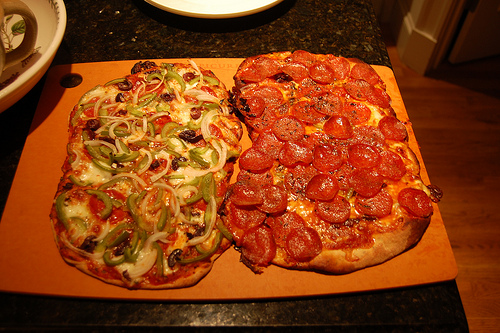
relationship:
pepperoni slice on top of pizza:
[284, 225, 322, 263] [213, 50, 444, 275]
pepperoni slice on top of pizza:
[399, 187, 434, 218] [213, 50, 444, 275]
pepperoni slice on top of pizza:
[306, 173, 341, 201] [213, 50, 444, 275]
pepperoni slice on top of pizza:
[323, 114, 355, 140] [213, 50, 444, 275]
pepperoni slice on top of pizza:
[378, 115, 408, 143] [213, 50, 444, 275]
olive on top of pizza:
[86, 118, 99, 130] [47, 59, 244, 290]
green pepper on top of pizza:
[165, 71, 187, 95] [47, 59, 244, 290]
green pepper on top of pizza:
[85, 184, 115, 218] [47, 59, 244, 290]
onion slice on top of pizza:
[200, 108, 221, 142] [47, 59, 244, 290]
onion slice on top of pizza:
[153, 175, 181, 223] [47, 59, 244, 290]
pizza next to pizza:
[213, 50, 444, 275] [47, 59, 244, 290]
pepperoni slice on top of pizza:
[309, 62, 335, 85] [213, 50, 444, 275]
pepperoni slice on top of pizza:
[350, 61, 380, 86] [213, 50, 444, 275]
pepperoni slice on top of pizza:
[236, 95, 266, 118] [213, 50, 444, 275]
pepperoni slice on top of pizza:
[239, 224, 275, 266] [213, 50, 444, 275]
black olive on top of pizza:
[131, 61, 144, 74] [47, 59, 244, 290]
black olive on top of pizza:
[168, 250, 183, 267] [47, 59, 244, 290]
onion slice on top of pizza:
[109, 174, 147, 188] [47, 59, 244, 290]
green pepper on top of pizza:
[55, 187, 72, 231] [47, 59, 244, 290]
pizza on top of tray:
[213, 50, 444, 275] [0, 56, 459, 302]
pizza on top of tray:
[47, 59, 244, 290] [0, 56, 459, 302]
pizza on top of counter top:
[213, 50, 444, 275] [0, 0, 468, 332]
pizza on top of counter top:
[47, 59, 244, 290] [0, 0, 468, 332]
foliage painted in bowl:
[12, 19, 26, 37] [0, 0, 67, 114]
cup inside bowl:
[1, 1, 39, 71] [0, 0, 67, 114]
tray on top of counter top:
[0, 56, 459, 302] [0, 0, 468, 332]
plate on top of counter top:
[143, 0, 285, 19] [0, 0, 468, 332]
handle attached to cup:
[4, 2, 39, 68] [1, 1, 39, 71]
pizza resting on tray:
[213, 50, 444, 275] [0, 56, 459, 302]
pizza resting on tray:
[47, 59, 244, 290] [0, 56, 459, 302]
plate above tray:
[143, 0, 285, 19] [0, 56, 459, 302]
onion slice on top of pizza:
[109, 120, 122, 140] [47, 59, 244, 290]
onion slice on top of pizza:
[188, 56, 204, 88] [47, 59, 244, 290]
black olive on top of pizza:
[86, 118, 99, 130] [47, 59, 244, 290]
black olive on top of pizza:
[80, 234, 97, 252] [47, 59, 244, 290]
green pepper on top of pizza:
[202, 171, 213, 203] [47, 59, 244, 290]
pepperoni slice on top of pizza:
[257, 186, 289, 214] [213, 50, 444, 275]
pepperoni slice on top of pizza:
[271, 115, 306, 143] [213, 50, 444, 275]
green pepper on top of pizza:
[125, 194, 151, 234] [47, 59, 244, 290]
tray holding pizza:
[0, 56, 459, 302] [213, 50, 444, 275]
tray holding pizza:
[0, 56, 459, 302] [47, 59, 244, 290]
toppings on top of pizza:
[58, 57, 236, 279] [47, 59, 244, 290]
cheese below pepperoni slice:
[362, 100, 382, 128] [343, 102, 371, 124]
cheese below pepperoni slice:
[271, 139, 430, 249] [399, 187, 434, 218]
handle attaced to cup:
[4, 2, 39, 68] [1, 1, 39, 71]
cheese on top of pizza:
[271, 139, 430, 249] [213, 50, 444, 275]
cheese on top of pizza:
[66, 201, 125, 269] [47, 59, 244, 290]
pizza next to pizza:
[47, 59, 244, 290] [213, 50, 444, 275]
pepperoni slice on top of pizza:
[241, 56, 280, 83] [213, 50, 444, 275]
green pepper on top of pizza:
[125, 98, 143, 119] [47, 59, 244, 290]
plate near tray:
[143, 0, 285, 19] [0, 56, 459, 302]